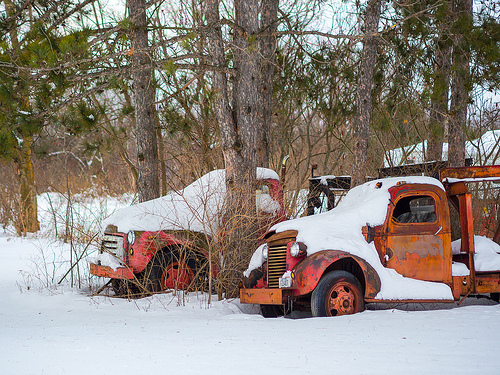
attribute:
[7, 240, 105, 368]
snow — thick, white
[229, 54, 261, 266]
tree bark — gray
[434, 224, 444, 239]
handle — silver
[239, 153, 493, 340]
truck — old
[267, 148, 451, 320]
old truck — very rusted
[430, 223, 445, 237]
handle — metal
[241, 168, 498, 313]
truck — orange, red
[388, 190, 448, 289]
door — red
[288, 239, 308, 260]
light — white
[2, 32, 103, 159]
tree needles — green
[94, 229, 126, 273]
grill — silver